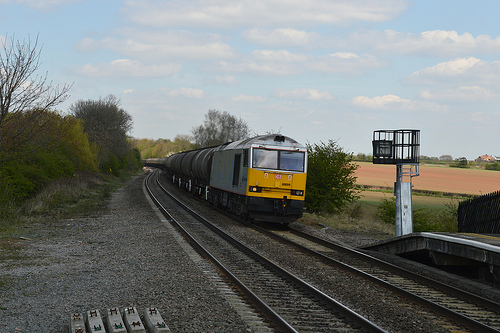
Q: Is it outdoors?
A: Yes, it is outdoors.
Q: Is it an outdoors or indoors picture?
A: It is outdoors.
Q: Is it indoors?
A: No, it is outdoors.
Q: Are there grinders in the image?
A: No, there are no grinders.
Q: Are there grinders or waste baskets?
A: No, there are no grinders or waste baskets.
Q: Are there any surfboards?
A: No, there are no surfboards.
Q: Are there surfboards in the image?
A: No, there are no surfboards.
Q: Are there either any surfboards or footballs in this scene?
A: No, there are no surfboards or footballs.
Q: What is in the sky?
A: The clouds are in the sky.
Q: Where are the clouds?
A: The clouds are in the sky.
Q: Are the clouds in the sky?
A: Yes, the clouds are in the sky.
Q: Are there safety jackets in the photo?
A: No, there are no safety jackets.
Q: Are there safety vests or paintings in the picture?
A: No, there are no safety vests or paintings.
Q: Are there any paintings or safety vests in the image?
A: No, there are no safety vests or paintings.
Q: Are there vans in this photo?
A: No, there are no vans.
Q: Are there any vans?
A: No, there are no vans.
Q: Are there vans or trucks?
A: No, there are no vans or trucks.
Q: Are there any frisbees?
A: No, there are no frisbees.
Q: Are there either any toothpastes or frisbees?
A: No, there are no frisbees or toothpastes.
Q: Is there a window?
A: Yes, there is a window.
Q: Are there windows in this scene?
A: Yes, there is a window.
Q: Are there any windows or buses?
A: Yes, there is a window.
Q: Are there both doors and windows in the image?
A: No, there is a window but no doors.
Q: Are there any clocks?
A: No, there are no clocks.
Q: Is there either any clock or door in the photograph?
A: No, there are no clocks or doors.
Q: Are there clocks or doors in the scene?
A: No, there are no clocks or doors.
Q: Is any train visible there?
A: Yes, there is a train.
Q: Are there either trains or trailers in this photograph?
A: Yes, there is a train.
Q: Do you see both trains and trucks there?
A: No, there is a train but no trucks.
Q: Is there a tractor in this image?
A: No, there are no tractors.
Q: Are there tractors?
A: No, there are no tractors.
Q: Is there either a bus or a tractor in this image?
A: No, there are no tractors or buses.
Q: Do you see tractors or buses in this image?
A: No, there are no tractors or buses.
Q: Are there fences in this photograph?
A: Yes, there is a fence.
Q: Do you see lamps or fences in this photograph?
A: Yes, there is a fence.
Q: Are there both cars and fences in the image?
A: Yes, there are both a fence and a car.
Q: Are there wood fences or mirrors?
A: Yes, there is a wood fence.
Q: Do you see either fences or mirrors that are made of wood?
A: Yes, the fence is made of wood.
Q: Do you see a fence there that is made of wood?
A: Yes, there is a fence that is made of wood.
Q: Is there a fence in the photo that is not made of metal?
A: Yes, there is a fence that is made of wood.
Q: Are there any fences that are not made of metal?
A: Yes, there is a fence that is made of wood.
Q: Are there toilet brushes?
A: No, there are no toilet brushes.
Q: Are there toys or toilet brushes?
A: No, there are no toilet brushes or toys.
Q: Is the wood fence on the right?
A: Yes, the fence is on the right of the image.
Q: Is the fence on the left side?
A: No, the fence is on the right of the image.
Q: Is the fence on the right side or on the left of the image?
A: The fence is on the right of the image.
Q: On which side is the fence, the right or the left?
A: The fence is on the right of the image.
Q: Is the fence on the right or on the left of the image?
A: The fence is on the right of the image.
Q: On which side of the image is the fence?
A: The fence is on the right of the image.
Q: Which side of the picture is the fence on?
A: The fence is on the right of the image.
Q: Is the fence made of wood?
A: Yes, the fence is made of wood.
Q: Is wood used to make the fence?
A: Yes, the fence is made of wood.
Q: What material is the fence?
A: The fence is made of wood.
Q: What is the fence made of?
A: The fence is made of wood.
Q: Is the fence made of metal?
A: No, the fence is made of wood.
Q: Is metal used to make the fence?
A: No, the fence is made of wood.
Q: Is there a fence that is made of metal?
A: No, there is a fence but it is made of wood.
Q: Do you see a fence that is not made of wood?
A: No, there is a fence but it is made of wood.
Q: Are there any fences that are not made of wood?
A: No, there is a fence but it is made of wood.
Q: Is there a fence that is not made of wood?
A: No, there is a fence but it is made of wood.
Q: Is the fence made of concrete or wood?
A: The fence is made of wood.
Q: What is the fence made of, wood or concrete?
A: The fence is made of wood.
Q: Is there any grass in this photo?
A: Yes, there is grass.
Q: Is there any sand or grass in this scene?
A: Yes, there is grass.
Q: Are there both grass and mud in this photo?
A: No, there is grass but no mud.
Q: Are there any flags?
A: No, there are no flags.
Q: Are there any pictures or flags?
A: No, there are no flags or pictures.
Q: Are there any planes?
A: No, there are no planes.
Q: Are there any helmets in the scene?
A: No, there are no helmets.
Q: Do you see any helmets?
A: No, there are no helmets.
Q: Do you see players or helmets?
A: No, there are no helmets or players.